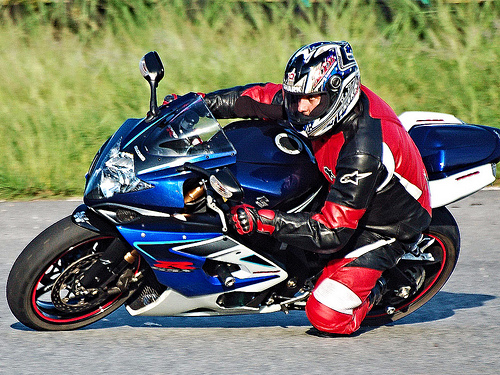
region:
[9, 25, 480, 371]
This is a motorcycle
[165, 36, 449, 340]
this is a person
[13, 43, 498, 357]
this is a bike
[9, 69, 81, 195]
this is grass on the ground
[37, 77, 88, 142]
this is grass on the ground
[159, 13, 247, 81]
this is grass on the ground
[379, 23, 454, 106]
this is grass on the ground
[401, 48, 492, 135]
this is grass on the ground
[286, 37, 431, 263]
this is a man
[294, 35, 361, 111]
this is a helmet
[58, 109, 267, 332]
this is a motorbike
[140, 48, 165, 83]
this is a mirror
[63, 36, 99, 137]
this is a grass area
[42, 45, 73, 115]
the leaves are green in color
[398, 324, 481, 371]
this is the road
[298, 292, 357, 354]
the knee is touching the ground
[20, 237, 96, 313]
this is the wheel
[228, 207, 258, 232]
this is a glove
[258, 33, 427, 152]
a man wearing a helmet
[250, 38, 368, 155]
the head of a man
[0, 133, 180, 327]
the front wheel on a motorcycle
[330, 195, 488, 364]
the back wheel on a motorcycle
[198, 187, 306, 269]
a man wearing gloves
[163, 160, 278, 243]
the handlebars on a motorcycle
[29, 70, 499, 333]
a man riding a blue motorcycle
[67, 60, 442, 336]
a man leaning on a motorcycle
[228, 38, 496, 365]
a man wearing a red jacket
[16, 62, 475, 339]
a man riding a motorcycle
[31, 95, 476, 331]
a man leaning over on a motorcycle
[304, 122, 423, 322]
the man;s red, white and black leather suit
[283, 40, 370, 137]
the man's white and black patterned helmet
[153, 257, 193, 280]
red logo on the side of the blue motorcycle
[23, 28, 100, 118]
long green grass growing next to the road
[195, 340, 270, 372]
grey asphalt surface of the road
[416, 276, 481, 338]
shadow of the motorcycle cast on the ground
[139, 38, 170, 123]
black side mirror of the motorcycle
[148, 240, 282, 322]
white trim of the blue motorcycle